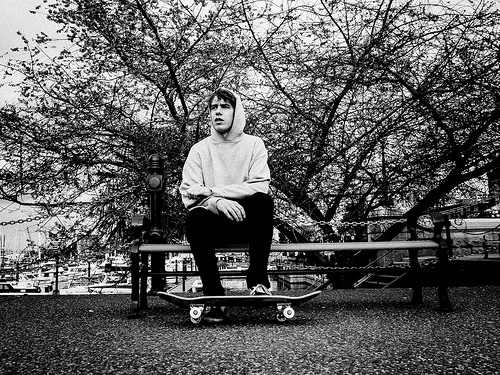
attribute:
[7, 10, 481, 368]
picture — black, white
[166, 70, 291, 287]
man — sitting, young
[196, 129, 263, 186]
hoodie — gray, white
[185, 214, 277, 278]
pants — black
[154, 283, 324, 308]
skateboard — black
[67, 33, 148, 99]
tree — branchy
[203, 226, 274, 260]
trousers — black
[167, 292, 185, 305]
rim — light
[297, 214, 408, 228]
chains — metal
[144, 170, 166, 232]
pole — metal, black